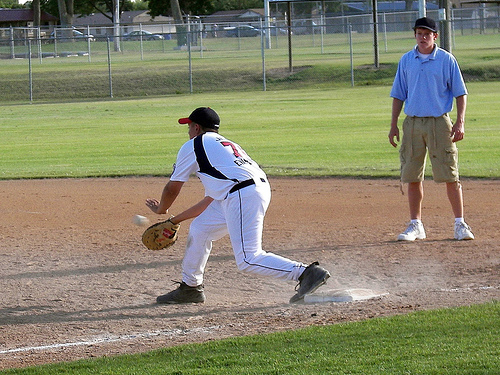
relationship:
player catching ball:
[173, 96, 320, 295] [134, 208, 165, 235]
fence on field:
[194, 22, 299, 85] [64, 112, 124, 162]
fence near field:
[194, 22, 299, 85] [64, 112, 124, 162]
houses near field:
[80, 10, 148, 30] [64, 112, 124, 162]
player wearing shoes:
[173, 96, 320, 295] [303, 251, 325, 290]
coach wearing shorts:
[388, 16, 482, 249] [403, 126, 459, 165]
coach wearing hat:
[388, 16, 482, 249] [406, 14, 438, 32]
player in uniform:
[173, 96, 320, 295] [198, 142, 269, 203]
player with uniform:
[173, 96, 320, 295] [198, 142, 269, 203]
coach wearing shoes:
[388, 16, 482, 249] [400, 224, 435, 243]